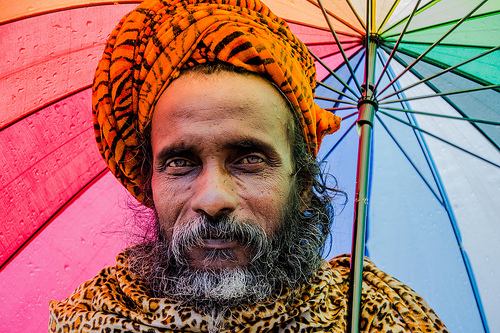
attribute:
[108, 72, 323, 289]
man — black, looking, old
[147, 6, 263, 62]
turban — orange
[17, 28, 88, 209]
umbrella — pink, colored, brown, pretty, red, purple, orange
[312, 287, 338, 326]
scarf — leopard, yellow